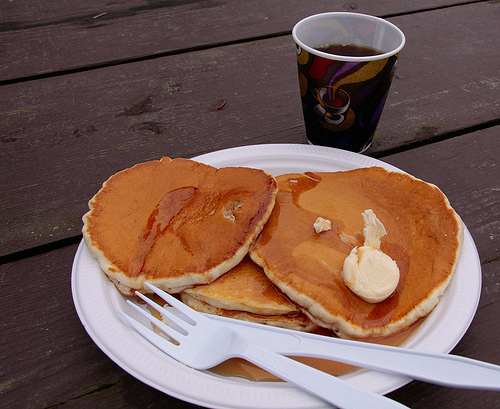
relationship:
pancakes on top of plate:
[83, 157, 461, 340] [71, 142, 482, 409]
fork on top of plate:
[117, 280, 409, 409] [71, 142, 482, 409]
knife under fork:
[156, 305, 499, 390] [117, 280, 409, 409]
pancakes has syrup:
[83, 157, 461, 340] [124, 186, 198, 274]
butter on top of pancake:
[313, 209, 424, 303] [83, 157, 461, 340]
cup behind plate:
[291, 11, 408, 155] [71, 142, 482, 409]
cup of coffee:
[291, 11, 408, 155] [313, 45, 384, 57]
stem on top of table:
[216, 102, 229, 110] [0, 1, 497, 407]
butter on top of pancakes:
[313, 209, 424, 303] [83, 157, 461, 340]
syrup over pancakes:
[124, 186, 198, 274] [83, 157, 461, 340]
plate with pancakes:
[71, 142, 482, 409] [83, 157, 461, 340]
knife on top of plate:
[156, 305, 499, 390] [71, 142, 482, 409]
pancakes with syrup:
[83, 157, 461, 340] [124, 186, 198, 274]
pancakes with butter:
[83, 157, 461, 340] [313, 209, 424, 303]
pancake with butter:
[83, 157, 461, 340] [313, 209, 424, 303]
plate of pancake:
[71, 142, 482, 409] [83, 157, 461, 340]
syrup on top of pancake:
[124, 186, 198, 274] [83, 157, 461, 340]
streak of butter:
[83, 157, 461, 340] [313, 209, 424, 303]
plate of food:
[71, 142, 482, 409] [83, 157, 461, 340]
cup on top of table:
[291, 11, 408, 155] [0, 1, 497, 407]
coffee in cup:
[313, 45, 384, 57] [291, 11, 408, 155]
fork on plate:
[117, 280, 409, 409] [71, 142, 482, 409]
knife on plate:
[156, 305, 499, 390] [71, 142, 482, 409]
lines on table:
[0, 1, 497, 407] [0, 1, 499, 408]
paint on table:
[0, 1, 497, 407] [0, 1, 499, 408]